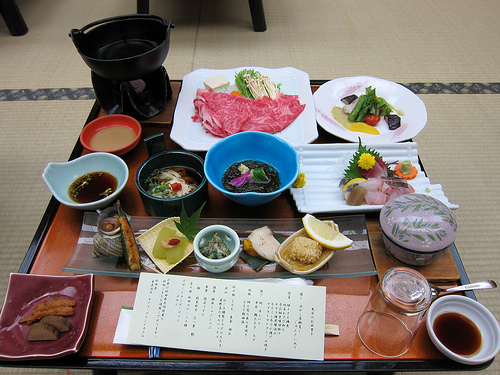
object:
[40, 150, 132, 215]
bow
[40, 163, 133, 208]
sauce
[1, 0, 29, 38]
leg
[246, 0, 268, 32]
leg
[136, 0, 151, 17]
leg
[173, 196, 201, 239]
leaf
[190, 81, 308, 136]
meat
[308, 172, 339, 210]
ground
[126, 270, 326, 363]
receipt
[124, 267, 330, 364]
menu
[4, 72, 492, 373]
table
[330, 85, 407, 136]
vegetables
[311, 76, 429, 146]
plate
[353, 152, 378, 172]
flower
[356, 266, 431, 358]
tglass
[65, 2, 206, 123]
cooking device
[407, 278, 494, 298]
spoon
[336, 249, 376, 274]
glass dish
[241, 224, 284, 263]
food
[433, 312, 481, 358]
liquid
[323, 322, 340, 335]
chopsticks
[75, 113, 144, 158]
bowl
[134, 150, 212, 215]
bowl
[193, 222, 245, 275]
bowl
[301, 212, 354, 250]
lemon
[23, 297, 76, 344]
meat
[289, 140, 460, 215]
plate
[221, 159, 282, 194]
caviar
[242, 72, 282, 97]
mushrooms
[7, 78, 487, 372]
tray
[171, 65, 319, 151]
plate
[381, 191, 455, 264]
dish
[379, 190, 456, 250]
lid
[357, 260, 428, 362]
glass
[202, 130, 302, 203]
bowl